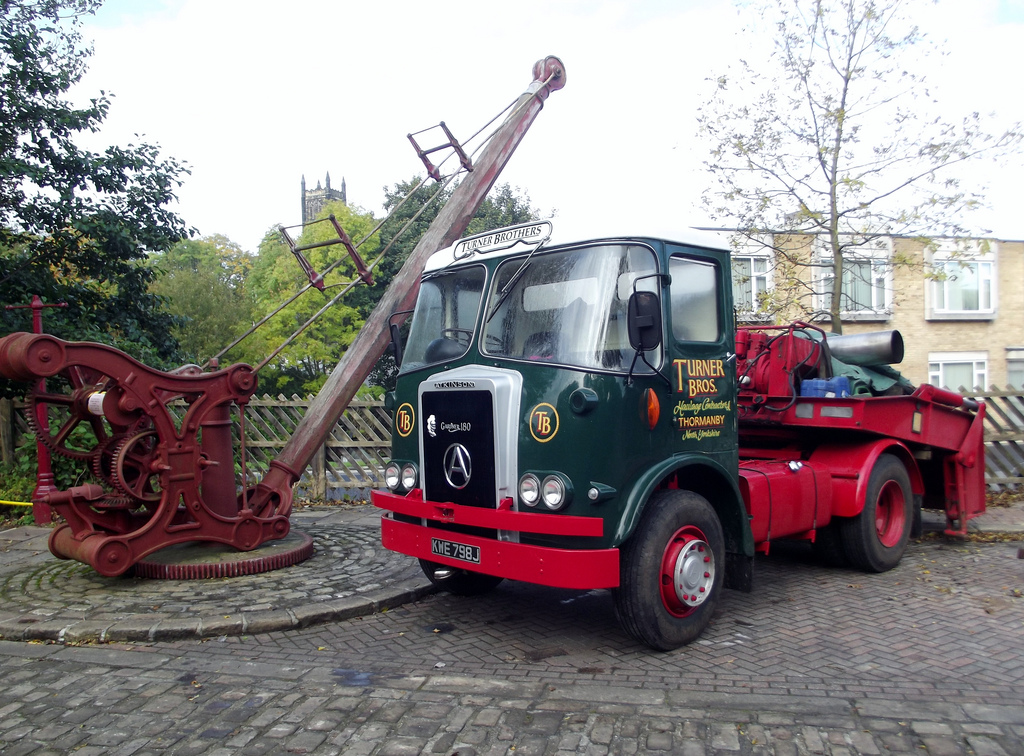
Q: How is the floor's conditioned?
A: Stained.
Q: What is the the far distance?
A: A tower.